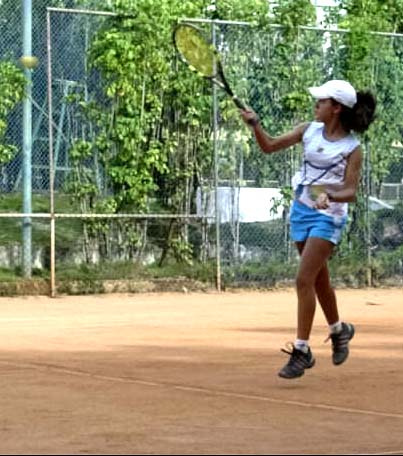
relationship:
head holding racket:
[314, 79, 356, 126] [164, 18, 249, 114]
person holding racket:
[240, 79, 376, 379] [171, 22, 250, 113]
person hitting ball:
[240, 79, 376, 379] [18, 51, 39, 71]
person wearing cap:
[240, 79, 376, 379] [305, 78, 355, 108]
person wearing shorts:
[240, 79, 376, 379] [286, 192, 350, 249]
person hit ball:
[240, 79, 376, 379] [20, 53, 37, 69]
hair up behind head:
[346, 92, 382, 135] [310, 84, 347, 131]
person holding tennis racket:
[292, 74, 358, 155] [166, 12, 233, 90]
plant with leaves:
[68, 2, 209, 259] [112, 34, 144, 97]